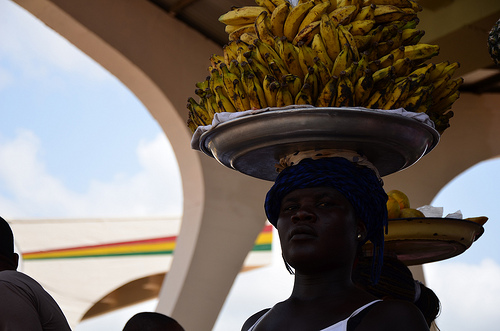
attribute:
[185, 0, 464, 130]
bananas — bunch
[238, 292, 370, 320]
tank top — white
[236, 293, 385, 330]
top — white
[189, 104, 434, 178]
plate — large, silver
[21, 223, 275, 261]
band — long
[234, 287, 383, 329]
top — white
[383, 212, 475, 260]
plate — yellow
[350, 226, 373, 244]
earing — white, small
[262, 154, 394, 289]
cloth — blue, wrap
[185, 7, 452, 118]
bananas — stack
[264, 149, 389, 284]
head — only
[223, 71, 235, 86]
banana — large amount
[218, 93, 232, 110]
banana — large amount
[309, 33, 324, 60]
banana — large amount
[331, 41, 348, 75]
banana — large amount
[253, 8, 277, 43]
banana — large amount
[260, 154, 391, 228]
wrap — blue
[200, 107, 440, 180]
plate — metal, round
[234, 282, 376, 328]
tank — white, spghetti string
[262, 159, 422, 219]
headscarf — blue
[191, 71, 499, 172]
platter — grey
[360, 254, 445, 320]
braids — hair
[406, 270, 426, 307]
white band — white 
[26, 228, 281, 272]
flag — red, yellow, green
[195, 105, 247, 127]
cloth — spread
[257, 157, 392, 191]
scarf — blue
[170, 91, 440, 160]
plate — large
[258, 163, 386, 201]
head wrap — blue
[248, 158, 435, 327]
woman — young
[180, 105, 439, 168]
plate — metal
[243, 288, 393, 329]
tank top — white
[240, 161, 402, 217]
bandana — blue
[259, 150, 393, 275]
headgear — blue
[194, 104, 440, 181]
tray — silver, white, metallic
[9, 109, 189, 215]
cloud — white